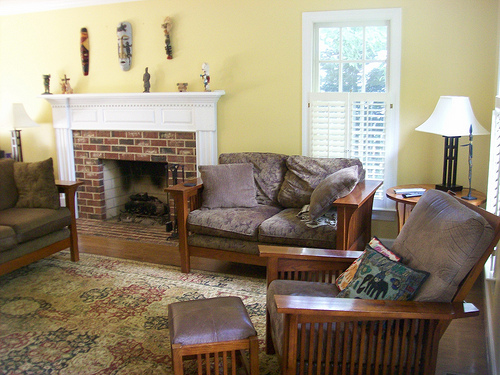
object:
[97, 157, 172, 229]
fireplace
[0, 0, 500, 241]
wall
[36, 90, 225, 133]
mantle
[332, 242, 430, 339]
pillow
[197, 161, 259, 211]
suede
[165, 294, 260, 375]
stool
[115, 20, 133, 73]
decorations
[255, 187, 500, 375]
recliner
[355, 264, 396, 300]
image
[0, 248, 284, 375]
rug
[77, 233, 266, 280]
flooring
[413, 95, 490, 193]
lamp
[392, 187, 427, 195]
controls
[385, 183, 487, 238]
tabel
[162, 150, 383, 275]
couch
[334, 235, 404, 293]
pillows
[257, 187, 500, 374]
chair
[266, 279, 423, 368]
seat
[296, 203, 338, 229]
control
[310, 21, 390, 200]
window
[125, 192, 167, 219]
wood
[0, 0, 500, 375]
room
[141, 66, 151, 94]
figures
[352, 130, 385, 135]
shutters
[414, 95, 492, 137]
lampshade